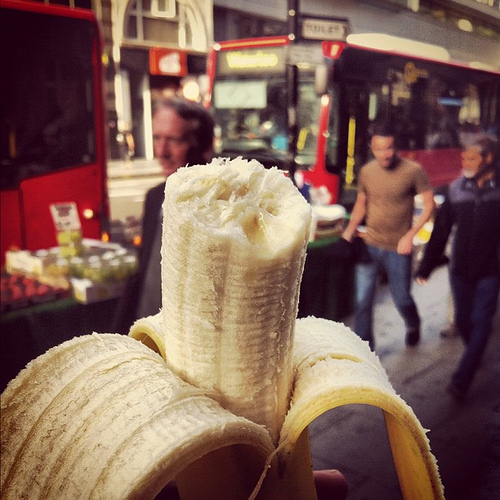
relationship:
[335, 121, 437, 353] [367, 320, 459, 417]
gentleman walking on a sidewalk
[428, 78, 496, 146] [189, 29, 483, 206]
window of a bus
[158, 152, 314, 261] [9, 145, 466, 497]
bite taken out of banana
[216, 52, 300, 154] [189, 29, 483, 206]
window on bus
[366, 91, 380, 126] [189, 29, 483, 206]
window of bus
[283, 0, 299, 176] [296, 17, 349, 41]
black pole with sign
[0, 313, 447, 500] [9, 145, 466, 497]
banana peel of banana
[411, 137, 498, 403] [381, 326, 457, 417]
gentleman walking on sidewalk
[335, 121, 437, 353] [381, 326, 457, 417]
gentleman walking on sidewalk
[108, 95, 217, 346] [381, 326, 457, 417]
man walking on sidewalk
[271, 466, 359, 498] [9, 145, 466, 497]
hand holding banana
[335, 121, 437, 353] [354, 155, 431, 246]
gentleman in brown shirt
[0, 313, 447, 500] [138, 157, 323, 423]
banana peel on banana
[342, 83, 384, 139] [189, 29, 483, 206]
window on bus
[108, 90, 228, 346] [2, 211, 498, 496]
man on street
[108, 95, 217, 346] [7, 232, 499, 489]
man on sidewalk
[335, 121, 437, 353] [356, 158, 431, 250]
gentleman in brown shirt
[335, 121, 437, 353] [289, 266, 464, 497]
gentleman walking on sidewalk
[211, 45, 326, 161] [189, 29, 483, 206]
window of bus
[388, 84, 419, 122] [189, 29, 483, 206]
window of bus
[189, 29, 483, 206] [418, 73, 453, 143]
bus has a window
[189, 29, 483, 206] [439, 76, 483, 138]
bus has a window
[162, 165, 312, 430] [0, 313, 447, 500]
banana has a banana peel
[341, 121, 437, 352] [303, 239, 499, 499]
gentleman walking on street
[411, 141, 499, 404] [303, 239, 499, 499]
gentleman walking on street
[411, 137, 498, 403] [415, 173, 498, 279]
gentleman wearing a shirt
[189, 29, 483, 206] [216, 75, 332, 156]
bus has a window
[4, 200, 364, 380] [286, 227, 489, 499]
table on sidewalk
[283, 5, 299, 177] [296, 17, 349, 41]
black pole has a sign